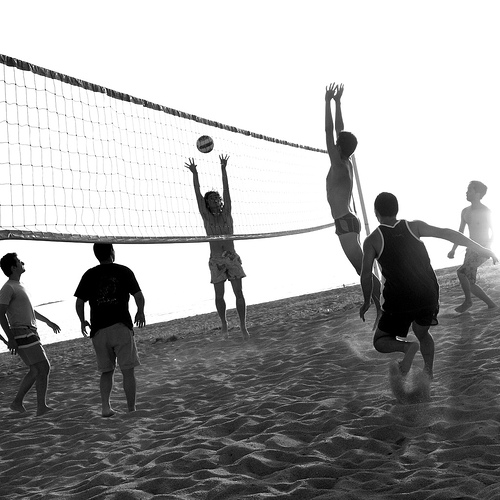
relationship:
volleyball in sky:
[194, 136, 212, 157] [240, 11, 260, 38]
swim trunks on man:
[205, 262, 228, 271] [315, 114, 361, 273]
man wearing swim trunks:
[315, 114, 361, 273] [205, 262, 228, 271]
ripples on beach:
[214, 385, 251, 415] [268, 394, 328, 476]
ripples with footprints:
[214, 385, 251, 415] [100, 434, 166, 468]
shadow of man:
[370, 419, 373, 422] [315, 114, 361, 273]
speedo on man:
[325, 212, 359, 235] [315, 114, 361, 273]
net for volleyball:
[45, 55, 121, 207] [194, 136, 212, 157]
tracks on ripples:
[232, 407, 310, 471] [214, 385, 251, 415]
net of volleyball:
[45, 55, 121, 207] [194, 136, 212, 157]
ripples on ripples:
[214, 385, 237, 411] [214, 385, 251, 415]